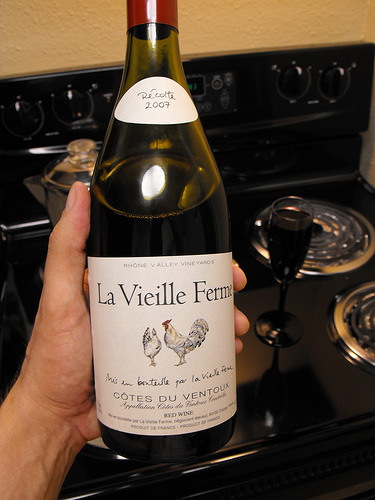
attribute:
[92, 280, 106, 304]
letter — black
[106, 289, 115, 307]
letter — black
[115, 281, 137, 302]
letter — black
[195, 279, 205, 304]
letter — black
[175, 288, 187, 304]
letter — black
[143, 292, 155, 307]
letter — black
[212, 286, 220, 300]
letter — black